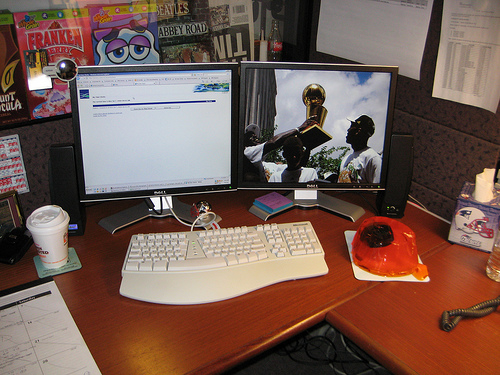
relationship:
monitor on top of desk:
[64, 44, 247, 210] [3, 186, 498, 374]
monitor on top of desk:
[235, 45, 404, 212] [3, 186, 498, 374]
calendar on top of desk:
[1, 268, 100, 374] [3, 186, 498, 374]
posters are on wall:
[3, 0, 269, 142] [1, 1, 499, 210]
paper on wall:
[425, 4, 500, 127] [1, 1, 499, 210]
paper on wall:
[313, 0, 433, 84] [1, 1, 499, 210]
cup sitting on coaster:
[20, 200, 79, 282] [25, 240, 85, 276]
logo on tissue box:
[459, 201, 475, 223] [444, 168, 498, 260]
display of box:
[2, 8, 166, 123] [13, 6, 94, 125]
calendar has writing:
[1, 268, 100, 374] [3, 310, 38, 373]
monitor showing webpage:
[64, 44, 247, 210] [81, 76, 228, 181]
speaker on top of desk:
[38, 135, 99, 238] [3, 186, 498, 374]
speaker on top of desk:
[383, 126, 415, 223] [3, 186, 498, 374]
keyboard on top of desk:
[112, 213, 339, 314] [3, 186, 498, 374]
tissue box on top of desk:
[444, 168, 498, 260] [3, 186, 498, 374]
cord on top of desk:
[439, 291, 499, 342] [3, 186, 498, 374]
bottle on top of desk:
[485, 216, 498, 280] [3, 186, 498, 374]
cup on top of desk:
[20, 200, 79, 282] [3, 186, 498, 374]